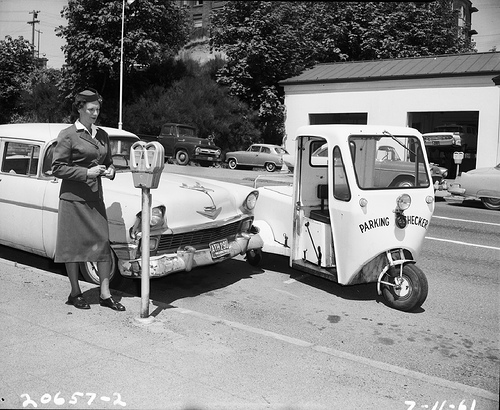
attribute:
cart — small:
[257, 122, 430, 310]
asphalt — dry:
[162, 170, 499, 393]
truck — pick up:
[138, 122, 224, 165]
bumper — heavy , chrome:
[124, 230, 257, 278]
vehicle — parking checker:
[28, 57, 286, 324]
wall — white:
[287, 85, 499, 180]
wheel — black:
[377, 256, 428, 313]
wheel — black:
[238, 223, 262, 270]